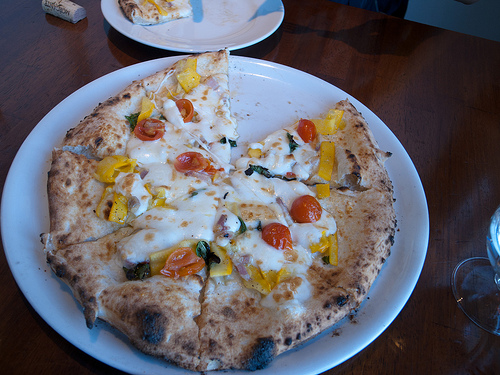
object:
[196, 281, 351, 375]
crust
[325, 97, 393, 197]
crust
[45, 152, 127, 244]
crust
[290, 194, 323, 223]
tomato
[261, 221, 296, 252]
tomato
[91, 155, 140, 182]
peppers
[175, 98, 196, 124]
tomato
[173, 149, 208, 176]
tomato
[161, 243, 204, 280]
tomato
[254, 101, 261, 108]
crumbs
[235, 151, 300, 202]
cheese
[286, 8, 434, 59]
shadow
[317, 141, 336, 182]
pepper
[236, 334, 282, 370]
area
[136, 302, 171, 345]
area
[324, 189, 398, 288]
pizza crust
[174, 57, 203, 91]
yellow pepper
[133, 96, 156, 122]
yellow pepper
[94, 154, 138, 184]
yellow pepper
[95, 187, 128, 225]
yellow pepper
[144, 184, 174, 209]
yellow pepper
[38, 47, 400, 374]
pizza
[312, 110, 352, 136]
peppers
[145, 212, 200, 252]
mozzarella cheese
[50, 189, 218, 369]
pizza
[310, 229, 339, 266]
toppings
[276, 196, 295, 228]
onion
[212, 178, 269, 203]
cheese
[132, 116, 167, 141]
tomato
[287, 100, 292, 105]
crumbs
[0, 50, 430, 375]
plate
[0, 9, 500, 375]
brown table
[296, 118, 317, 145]
cherry tomato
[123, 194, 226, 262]
cheese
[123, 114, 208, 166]
cheese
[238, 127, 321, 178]
cheese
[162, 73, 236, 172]
cheese